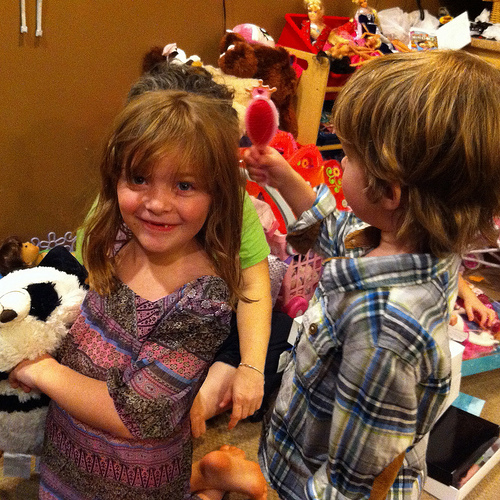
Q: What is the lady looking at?
A: The camera.